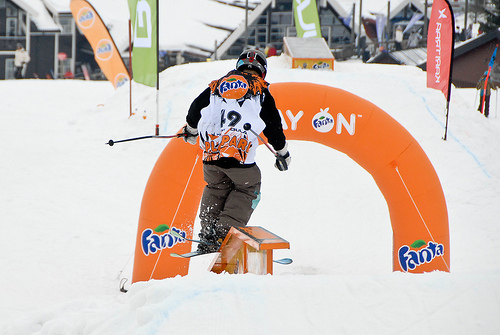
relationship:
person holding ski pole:
[180, 47, 290, 250] [244, 123, 278, 159]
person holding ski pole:
[180, 47, 290, 250] [105, 131, 191, 148]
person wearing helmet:
[180, 47, 290, 250] [237, 48, 268, 76]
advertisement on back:
[219, 74, 248, 99] [197, 72, 265, 165]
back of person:
[197, 72, 265, 165] [180, 47, 290, 250]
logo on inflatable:
[398, 241, 443, 272] [134, 81, 451, 282]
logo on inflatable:
[141, 223, 187, 255] [134, 81, 451, 282]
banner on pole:
[427, 1, 451, 98] [442, 1, 456, 141]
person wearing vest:
[180, 47, 290, 250] [195, 69, 264, 166]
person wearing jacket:
[180, 47, 290, 250] [186, 69, 286, 168]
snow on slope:
[1, 58, 499, 334] [110, 55, 492, 334]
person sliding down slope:
[180, 47, 290, 250] [110, 55, 492, 334]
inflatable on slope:
[134, 81, 451, 282] [110, 55, 492, 334]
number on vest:
[219, 108, 242, 128] [195, 69, 264, 166]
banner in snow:
[427, 1, 451, 98] [1, 58, 499, 334]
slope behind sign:
[110, 55, 492, 334] [126, 1, 158, 89]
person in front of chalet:
[12, 41, 29, 77] [0, 0, 109, 82]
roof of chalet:
[16, 0, 82, 32] [0, 0, 109, 82]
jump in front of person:
[282, 35, 334, 70] [180, 47, 290, 250]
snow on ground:
[1, 58, 499, 334] [4, 61, 499, 333]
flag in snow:
[293, 0, 321, 37] [1, 58, 499, 334]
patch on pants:
[252, 192, 261, 212] [199, 162, 260, 242]